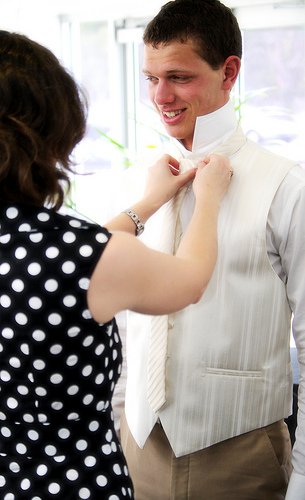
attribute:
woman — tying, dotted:
[1, 29, 232, 500]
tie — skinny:
[122, 314, 164, 450]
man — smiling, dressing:
[140, 1, 303, 500]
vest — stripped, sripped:
[124, 130, 296, 459]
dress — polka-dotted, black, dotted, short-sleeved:
[1, 208, 135, 500]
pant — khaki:
[123, 415, 292, 500]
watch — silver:
[125, 208, 144, 235]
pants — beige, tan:
[118, 411, 292, 499]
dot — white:
[45, 279, 57, 293]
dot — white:
[48, 310, 60, 324]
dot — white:
[76, 244, 94, 256]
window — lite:
[76, 14, 142, 189]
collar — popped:
[191, 102, 228, 150]